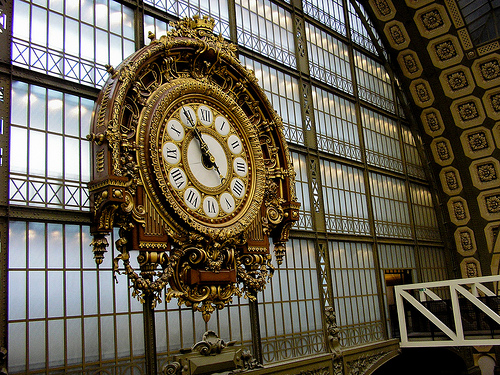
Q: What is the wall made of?
A: Glass and metal.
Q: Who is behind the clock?
A: No one.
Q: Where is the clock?
A: Hanging on the wall.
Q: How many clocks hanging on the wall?
A: One.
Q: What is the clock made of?
A: Gold and wood.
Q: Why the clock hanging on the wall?
A: For display.